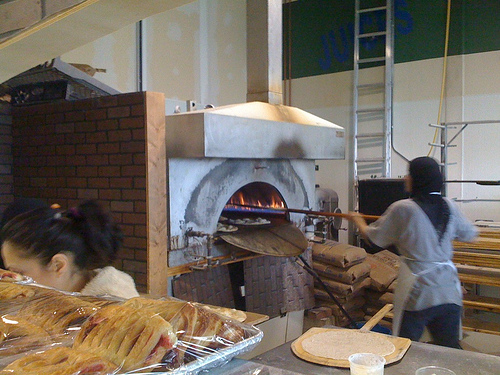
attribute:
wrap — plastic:
[4, 284, 217, 372]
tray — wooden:
[289, 302, 415, 369]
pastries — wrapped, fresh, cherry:
[0, 266, 260, 375]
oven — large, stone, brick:
[166, 101, 350, 317]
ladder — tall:
[351, 0, 394, 255]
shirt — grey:
[370, 199, 483, 307]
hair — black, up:
[3, 198, 126, 264]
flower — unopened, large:
[311, 238, 399, 324]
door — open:
[219, 220, 308, 260]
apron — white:
[392, 260, 458, 337]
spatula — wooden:
[233, 199, 377, 227]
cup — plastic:
[344, 352, 398, 374]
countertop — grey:
[241, 333, 499, 372]